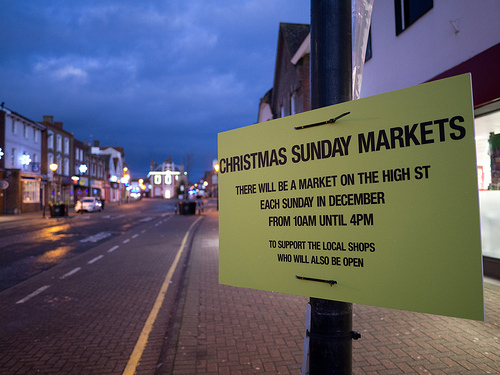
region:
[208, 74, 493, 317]
advertisement for a sale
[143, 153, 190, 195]
building with lit rooms at end of street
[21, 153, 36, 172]
light hanging off building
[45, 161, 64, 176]
light on the street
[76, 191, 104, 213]
vehicle on the street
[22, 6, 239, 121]
a blue sky with clouds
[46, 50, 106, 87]
cloud in the sky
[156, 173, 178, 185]
windows in the building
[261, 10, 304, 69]
pointed top of building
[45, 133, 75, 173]
set of windows on building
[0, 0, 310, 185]
the clouds in the sky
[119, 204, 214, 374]
the yellow line on the ground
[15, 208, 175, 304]
the white lines on the road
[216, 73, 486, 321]
the sign on the pole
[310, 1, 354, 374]
the black pole behind the sign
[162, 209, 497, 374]
the wide sidewalk the pole is on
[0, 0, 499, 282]
the buildings on the sides of the road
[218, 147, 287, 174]
the word "CHRISTMAS" on the sign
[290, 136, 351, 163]
the word "SUNDAY" on the sign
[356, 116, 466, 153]
the word "MARKETS" on the sign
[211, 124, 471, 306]
Yellow sing on pole.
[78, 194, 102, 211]
White car parked on side of road.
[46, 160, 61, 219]
Light pole on top of side walk.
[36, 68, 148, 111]
Thin white clouds in the sky.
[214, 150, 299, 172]
Black letters on top of yellow board.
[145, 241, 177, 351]
Yellow no crossing line.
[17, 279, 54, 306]
Broken up white passing line.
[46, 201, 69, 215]
Group of trash cans on sidewalk.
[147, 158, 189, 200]
Small building lit up at the end of road.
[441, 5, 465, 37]
Flag pole stand on side of building.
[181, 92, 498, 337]
yellow sign on the pole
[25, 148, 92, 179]
street lights on the sidewalk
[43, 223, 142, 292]
white lines painted on the road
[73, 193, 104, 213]
car parked on the street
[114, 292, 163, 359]
yellow line down the street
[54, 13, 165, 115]
clouds in the darkening sky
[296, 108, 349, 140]
zip tie holding sign on pole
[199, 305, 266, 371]
brick sidewalk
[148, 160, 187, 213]
building at the end of the street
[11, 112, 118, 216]
buildings across the street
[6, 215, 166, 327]
white lines painted on a street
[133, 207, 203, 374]
a yellow line painted on a street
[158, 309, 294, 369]
a red brick side walk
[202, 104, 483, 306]
a yellow sign with black letters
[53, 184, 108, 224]
a white car parked on the side of a street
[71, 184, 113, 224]
a car parked at the curb of a street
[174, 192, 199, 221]
a garbage dumpster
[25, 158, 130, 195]
street lights on a post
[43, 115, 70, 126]
a chimney on top of a building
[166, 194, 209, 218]
post around a garbage dumpster